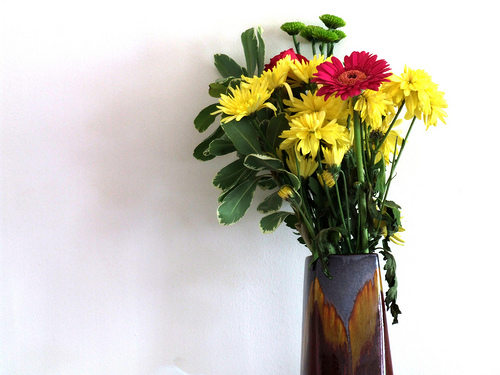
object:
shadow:
[69, 41, 228, 320]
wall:
[0, 8, 253, 372]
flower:
[280, 20, 303, 47]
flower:
[301, 16, 346, 53]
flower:
[266, 45, 310, 68]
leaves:
[204, 26, 269, 106]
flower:
[353, 88, 400, 133]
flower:
[289, 54, 326, 82]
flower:
[214, 55, 319, 121]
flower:
[279, 110, 349, 185]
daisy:
[309, 50, 390, 98]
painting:
[312, 276, 370, 318]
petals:
[418, 90, 428, 117]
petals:
[429, 88, 446, 113]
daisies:
[216, 63, 278, 123]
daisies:
[278, 104, 343, 154]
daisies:
[399, 66, 445, 125]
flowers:
[278, 11, 342, 59]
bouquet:
[193, 12, 446, 324]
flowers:
[310, 50, 446, 177]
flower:
[376, 66, 447, 126]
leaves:
[216, 116, 262, 157]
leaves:
[211, 157, 260, 224]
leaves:
[245, 113, 295, 193]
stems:
[349, 120, 373, 195]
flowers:
[279, 6, 353, 55]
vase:
[300, 250, 390, 375]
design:
[311, 271, 381, 370]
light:
[377, 259, 387, 373]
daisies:
[211, 49, 449, 247]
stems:
[292, 198, 379, 251]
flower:
[275, 185, 294, 195]